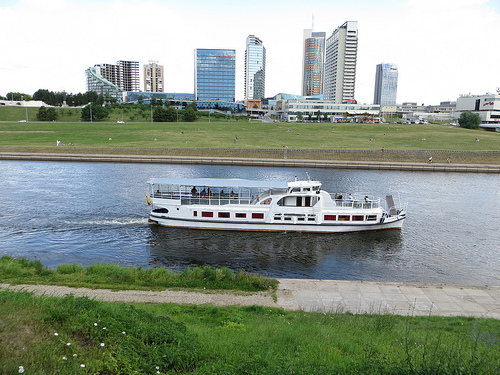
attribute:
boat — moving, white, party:
[142, 178, 407, 235]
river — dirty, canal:
[0, 158, 498, 284]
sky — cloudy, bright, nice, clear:
[1, 0, 499, 101]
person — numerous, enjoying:
[191, 185, 199, 199]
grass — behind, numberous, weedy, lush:
[0, 247, 274, 294]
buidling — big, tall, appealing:
[242, 35, 265, 105]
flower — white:
[98, 342, 106, 348]